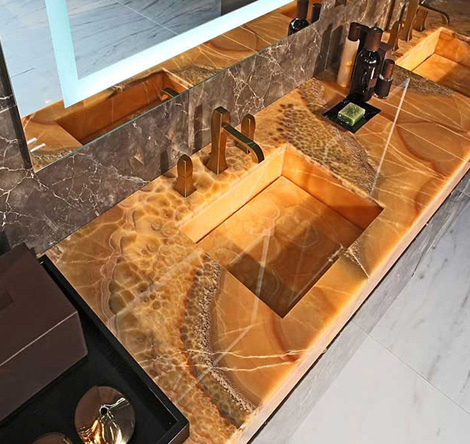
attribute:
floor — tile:
[251, 168, 468, 442]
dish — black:
[309, 90, 388, 143]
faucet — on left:
[208, 99, 268, 174]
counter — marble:
[2, 20, 468, 440]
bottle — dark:
[351, 28, 381, 101]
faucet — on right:
[200, 108, 261, 163]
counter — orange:
[41, 0, 468, 443]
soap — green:
[336, 100, 367, 126]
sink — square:
[166, 128, 440, 325]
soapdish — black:
[324, 90, 381, 134]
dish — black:
[322, 94, 382, 134]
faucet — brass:
[202, 98, 268, 185]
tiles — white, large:
[251, 170, 467, 441]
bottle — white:
[342, 18, 380, 88]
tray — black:
[2, 224, 228, 438]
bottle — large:
[345, 25, 381, 100]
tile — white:
[237, 317, 467, 440]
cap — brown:
[350, 24, 363, 41]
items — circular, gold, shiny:
[177, 105, 265, 193]